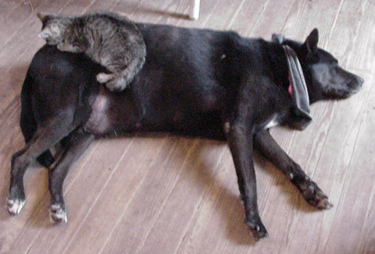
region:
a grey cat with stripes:
[30, 6, 162, 97]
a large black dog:
[6, 19, 367, 243]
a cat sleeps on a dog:
[5, 9, 374, 230]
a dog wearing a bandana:
[248, 18, 368, 141]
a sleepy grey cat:
[27, 5, 166, 100]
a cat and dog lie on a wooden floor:
[6, 10, 372, 237]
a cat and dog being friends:
[5, 6, 373, 240]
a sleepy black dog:
[3, 9, 369, 240]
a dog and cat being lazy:
[4, 5, 363, 251]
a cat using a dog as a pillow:
[30, 3, 156, 96]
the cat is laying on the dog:
[11, 8, 365, 244]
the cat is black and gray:
[24, 4, 161, 93]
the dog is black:
[8, 10, 358, 238]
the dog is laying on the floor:
[6, 2, 367, 250]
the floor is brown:
[20, 124, 374, 250]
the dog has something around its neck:
[250, 20, 360, 143]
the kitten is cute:
[30, 4, 168, 104]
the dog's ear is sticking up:
[287, 21, 365, 119]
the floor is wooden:
[4, 99, 364, 252]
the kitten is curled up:
[31, 6, 153, 92]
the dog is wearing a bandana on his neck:
[258, 29, 321, 130]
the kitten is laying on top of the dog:
[31, 9, 175, 88]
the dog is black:
[164, 42, 263, 128]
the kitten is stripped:
[31, 2, 173, 107]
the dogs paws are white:
[0, 184, 69, 226]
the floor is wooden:
[114, 158, 211, 236]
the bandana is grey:
[264, 22, 319, 129]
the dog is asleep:
[277, 19, 370, 120]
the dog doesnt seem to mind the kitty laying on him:
[3, 5, 350, 218]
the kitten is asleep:
[33, 9, 147, 97]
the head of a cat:
[34, 9, 74, 47]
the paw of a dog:
[45, 200, 69, 228]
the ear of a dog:
[299, 25, 321, 56]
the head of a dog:
[284, 26, 374, 104]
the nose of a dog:
[355, 72, 368, 85]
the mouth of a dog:
[324, 84, 360, 93]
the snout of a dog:
[324, 66, 368, 101]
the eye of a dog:
[328, 56, 339, 68]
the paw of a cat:
[95, 69, 108, 82]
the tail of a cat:
[103, 54, 151, 93]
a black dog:
[6, 21, 364, 240]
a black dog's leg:
[229, 115, 269, 245]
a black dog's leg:
[250, 119, 333, 220]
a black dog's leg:
[48, 127, 88, 229]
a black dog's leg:
[7, 110, 65, 225]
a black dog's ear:
[297, 23, 321, 54]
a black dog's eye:
[328, 57, 338, 68]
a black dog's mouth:
[334, 69, 362, 95]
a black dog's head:
[295, 28, 360, 107]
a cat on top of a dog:
[29, 2, 147, 100]